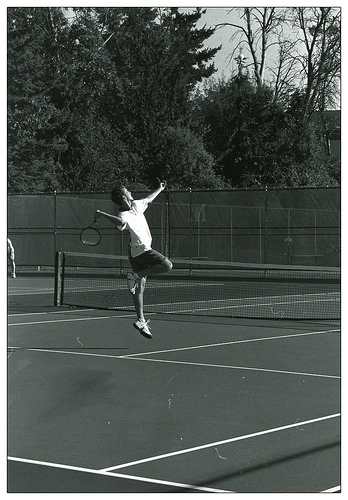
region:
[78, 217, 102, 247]
The man tennis racket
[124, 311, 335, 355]
The lines on the tennis court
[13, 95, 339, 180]
The trees behind the tennis court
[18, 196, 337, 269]
The fence on the tennis court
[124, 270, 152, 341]
The tennis players shoes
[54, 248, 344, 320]
The tennis court net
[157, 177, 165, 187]
The tennis player ball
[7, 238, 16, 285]
The person off camera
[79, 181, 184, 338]
A tennis player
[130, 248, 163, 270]
The tennis players shorts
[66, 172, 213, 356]
MAN JUMPING IN AIR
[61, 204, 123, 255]
TENNIS RACKET IN MAN'S RIGHT HAND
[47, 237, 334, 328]
NET ON TENNIS COURT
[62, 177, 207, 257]
MAN SWINGING TENNIS RACKET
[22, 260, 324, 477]
LARGE TENNIS COURT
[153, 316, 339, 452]
WHITE LINES ON TENNIS COURT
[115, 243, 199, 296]
TENNIS PLAYER HAS RIGHT LEG BENT AT KNEE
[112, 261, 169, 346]
MAN IS WEARING TENNIS SHOES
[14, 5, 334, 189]
MULTIPLE TREES IN BACKGROUND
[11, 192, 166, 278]
TARP ON FENCE AT SIDE OF TENNIS COURT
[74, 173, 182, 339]
player jumping to hit the ball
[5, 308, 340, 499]
white lines on the tennis court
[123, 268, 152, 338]
shoes of the tennis player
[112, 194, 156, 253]
white shirt of the tennis player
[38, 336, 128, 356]
shadow of player on the court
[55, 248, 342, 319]
black net across the court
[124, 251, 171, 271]
shorts of the tennis player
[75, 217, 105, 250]
racket of the tennis player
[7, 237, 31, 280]
tennis player in the background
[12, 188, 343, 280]
fenceline along the tennis court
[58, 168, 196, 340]
A person playing tennis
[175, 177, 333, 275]
A tall long fence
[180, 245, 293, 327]
A tennis net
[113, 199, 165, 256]
A person wearing a white shirt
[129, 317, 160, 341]
A person wearing white tennsi shoes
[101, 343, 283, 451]
A tennis court with white divider lines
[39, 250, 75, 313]
Post holding a tennis net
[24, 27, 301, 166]
Trees on other side of fence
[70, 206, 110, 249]
A person holding a tennis racket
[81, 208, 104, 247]
tennis racquet mid swing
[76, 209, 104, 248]
person swinging tennis racquet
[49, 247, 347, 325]
tennis netting on court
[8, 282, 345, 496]
tennis court with netting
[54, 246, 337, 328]
dividing net for tennis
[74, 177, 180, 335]
person swinging tennis racquet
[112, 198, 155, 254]
person wearing tee shirt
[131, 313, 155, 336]
tennis shoes on player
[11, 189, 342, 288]
fencing around perimeter of tennis courts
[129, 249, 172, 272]
person wearing shorts while playing tennis